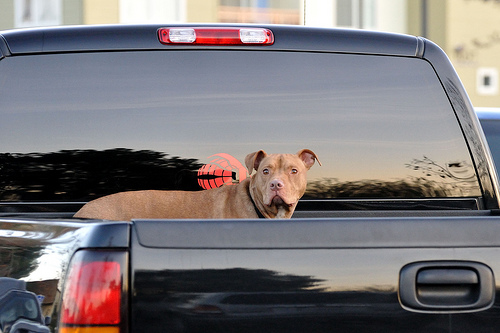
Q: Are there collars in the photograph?
A: Yes, there is a collar.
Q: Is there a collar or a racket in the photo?
A: Yes, there is a collar.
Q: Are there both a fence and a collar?
A: No, there is a collar but no fences.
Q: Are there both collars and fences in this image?
A: No, there is a collar but no fences.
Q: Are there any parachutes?
A: No, there are no parachutes.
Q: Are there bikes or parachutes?
A: No, there are no parachutes or bikes.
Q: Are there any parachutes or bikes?
A: No, there are no parachutes or bikes.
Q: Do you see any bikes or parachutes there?
A: No, there are no parachutes or bikes.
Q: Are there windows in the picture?
A: Yes, there is a window.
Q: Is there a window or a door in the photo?
A: Yes, there is a window.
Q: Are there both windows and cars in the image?
A: Yes, there are both a window and a car.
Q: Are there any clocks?
A: No, there are no clocks.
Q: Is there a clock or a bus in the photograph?
A: No, there are no clocks or buses.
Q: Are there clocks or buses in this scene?
A: No, there are no clocks or buses.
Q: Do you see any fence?
A: No, there are no fences.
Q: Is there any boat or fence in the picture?
A: No, there are no fences or boats.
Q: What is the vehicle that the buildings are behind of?
A: The vehicle is a car.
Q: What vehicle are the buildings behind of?
A: The buildings are behind the car.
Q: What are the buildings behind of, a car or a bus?
A: The buildings are behind a car.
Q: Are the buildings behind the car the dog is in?
A: Yes, the buildings are behind the car.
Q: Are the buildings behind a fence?
A: No, the buildings are behind the car.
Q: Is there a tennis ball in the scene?
A: No, there are no tennis balls.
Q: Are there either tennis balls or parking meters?
A: No, there are no tennis balls or parking meters.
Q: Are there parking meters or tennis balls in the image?
A: No, there are no tennis balls or parking meters.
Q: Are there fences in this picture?
A: No, there are no fences.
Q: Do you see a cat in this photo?
A: No, there are no cats.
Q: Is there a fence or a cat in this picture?
A: No, there are no cats or fences.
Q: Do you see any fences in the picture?
A: No, there are no fences.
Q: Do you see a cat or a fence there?
A: No, there are no fences or cats.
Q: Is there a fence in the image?
A: No, there are no fences.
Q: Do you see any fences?
A: No, there are no fences.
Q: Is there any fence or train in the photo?
A: No, there are no fences or trains.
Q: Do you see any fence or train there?
A: No, there are no fences or trains.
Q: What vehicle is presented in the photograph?
A: The vehicle is a car.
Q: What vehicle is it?
A: The vehicle is a car.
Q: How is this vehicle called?
A: This is a car.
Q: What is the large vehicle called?
A: The vehicle is a car.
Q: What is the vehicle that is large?
A: The vehicle is a car.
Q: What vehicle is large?
A: The vehicle is a car.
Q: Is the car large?
A: Yes, the car is large.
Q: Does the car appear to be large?
A: Yes, the car is large.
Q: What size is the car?
A: The car is large.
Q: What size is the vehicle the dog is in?
A: The car is large.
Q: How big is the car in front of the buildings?
A: The car is large.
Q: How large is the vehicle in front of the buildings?
A: The car is large.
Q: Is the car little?
A: No, the car is large.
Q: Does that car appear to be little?
A: No, the car is large.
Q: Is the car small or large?
A: The car is large.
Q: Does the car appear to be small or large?
A: The car is large.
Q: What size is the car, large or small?
A: The car is large.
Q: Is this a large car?
A: Yes, this is a large car.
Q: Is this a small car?
A: No, this is a large car.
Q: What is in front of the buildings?
A: The car is in front of the buildings.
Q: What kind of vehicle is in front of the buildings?
A: The vehicle is a car.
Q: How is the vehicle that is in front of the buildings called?
A: The vehicle is a car.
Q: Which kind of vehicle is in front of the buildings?
A: The vehicle is a car.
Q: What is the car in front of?
A: The car is in front of the buildings.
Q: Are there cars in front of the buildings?
A: Yes, there is a car in front of the buildings.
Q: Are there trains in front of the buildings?
A: No, there is a car in front of the buildings.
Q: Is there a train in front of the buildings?
A: No, there is a car in front of the buildings.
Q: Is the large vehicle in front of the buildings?
A: Yes, the car is in front of the buildings.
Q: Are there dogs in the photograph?
A: Yes, there is a dog.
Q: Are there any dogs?
A: Yes, there is a dog.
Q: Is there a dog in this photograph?
A: Yes, there is a dog.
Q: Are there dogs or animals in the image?
A: Yes, there is a dog.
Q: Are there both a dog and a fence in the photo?
A: No, there is a dog but no fences.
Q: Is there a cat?
A: No, there are no cats.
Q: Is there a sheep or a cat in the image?
A: No, there are no cats or sheep.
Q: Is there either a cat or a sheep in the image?
A: No, there are no cats or sheep.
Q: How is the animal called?
A: The animal is a dog.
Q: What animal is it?
A: The animal is a dog.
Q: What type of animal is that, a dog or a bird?
A: This is a dog.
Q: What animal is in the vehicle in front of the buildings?
A: The dog is in the car.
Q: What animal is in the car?
A: The dog is in the car.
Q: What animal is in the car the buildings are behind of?
A: The animal is a dog.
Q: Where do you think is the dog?
A: The dog is in the car.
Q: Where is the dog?
A: The dog is in the car.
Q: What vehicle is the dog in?
A: The dog is in the car.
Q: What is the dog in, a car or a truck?
A: The dog is in a car.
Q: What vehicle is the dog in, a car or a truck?
A: The dog is in a car.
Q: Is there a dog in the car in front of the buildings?
A: Yes, there is a dog in the car.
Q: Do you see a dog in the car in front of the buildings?
A: Yes, there is a dog in the car.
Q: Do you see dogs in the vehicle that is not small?
A: Yes, there is a dog in the car.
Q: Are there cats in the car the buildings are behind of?
A: No, there is a dog in the car.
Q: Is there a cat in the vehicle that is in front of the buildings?
A: No, there is a dog in the car.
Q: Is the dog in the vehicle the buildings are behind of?
A: Yes, the dog is in the car.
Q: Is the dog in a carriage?
A: No, the dog is in the car.